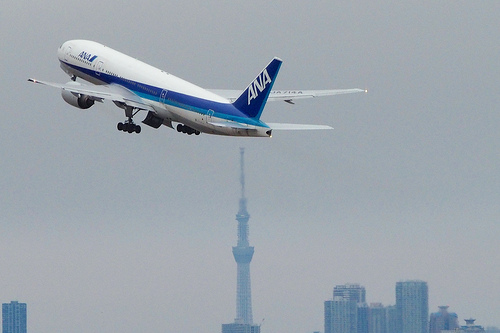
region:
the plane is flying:
[29, 22, 320, 179]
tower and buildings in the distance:
[216, 141, 450, 331]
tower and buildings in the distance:
[207, 127, 280, 329]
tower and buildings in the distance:
[305, 265, 470, 331]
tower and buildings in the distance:
[7, 249, 473, 329]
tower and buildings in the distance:
[9, 152, 478, 330]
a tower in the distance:
[224, 143, 296, 326]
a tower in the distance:
[232, 146, 261, 299]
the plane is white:
[59, 35, 318, 185]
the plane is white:
[57, 37, 204, 124]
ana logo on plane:
[222, 73, 285, 103]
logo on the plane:
[68, 33, 115, 73]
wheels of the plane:
[108, 114, 153, 135]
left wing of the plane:
[34, 73, 159, 136]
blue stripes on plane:
[112, 63, 227, 130]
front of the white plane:
[45, 34, 102, 72]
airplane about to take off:
[30, 31, 282, 172]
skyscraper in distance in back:
[200, 208, 277, 321]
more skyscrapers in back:
[305, 255, 451, 330]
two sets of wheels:
[106, 116, 202, 146]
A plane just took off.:
[36, 36, 286, 143]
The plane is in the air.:
[26, 22, 311, 140]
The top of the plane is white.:
[100, 51, 133, 69]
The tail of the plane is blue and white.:
[241, 50, 276, 115]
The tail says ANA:
[239, 58, 272, 118]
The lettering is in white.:
[234, 69, 275, 114]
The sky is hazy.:
[400, 61, 450, 136]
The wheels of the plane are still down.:
[102, 112, 203, 143]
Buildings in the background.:
[272, 275, 440, 329]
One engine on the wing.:
[57, 82, 108, 114]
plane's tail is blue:
[207, 47, 281, 164]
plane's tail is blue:
[224, 59, 309, 173]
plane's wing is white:
[34, 71, 169, 158]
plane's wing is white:
[210, 79, 370, 119]